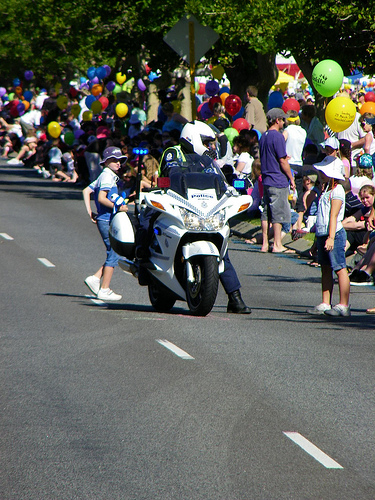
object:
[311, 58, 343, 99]
balloon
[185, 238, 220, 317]
wheel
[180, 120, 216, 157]
helmet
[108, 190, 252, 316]
bike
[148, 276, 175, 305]
tire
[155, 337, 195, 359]
line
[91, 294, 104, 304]
line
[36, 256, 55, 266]
line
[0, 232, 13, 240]
line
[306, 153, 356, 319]
child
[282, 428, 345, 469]
white line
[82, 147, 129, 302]
child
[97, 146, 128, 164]
dark hat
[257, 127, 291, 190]
purple shirt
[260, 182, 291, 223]
shorts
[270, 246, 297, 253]
flip flop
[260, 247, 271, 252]
flip flop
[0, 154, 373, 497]
road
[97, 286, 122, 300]
white shoes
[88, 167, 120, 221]
shirt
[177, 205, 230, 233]
headlights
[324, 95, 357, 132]
balloon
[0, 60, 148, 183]
people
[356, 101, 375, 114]
balloons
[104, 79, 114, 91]
balloon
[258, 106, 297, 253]
man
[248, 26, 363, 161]
air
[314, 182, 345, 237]
shirt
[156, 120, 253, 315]
man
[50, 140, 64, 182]
person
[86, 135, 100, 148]
person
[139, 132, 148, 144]
person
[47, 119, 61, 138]
balloon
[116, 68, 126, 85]
balloon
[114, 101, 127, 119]
balloon